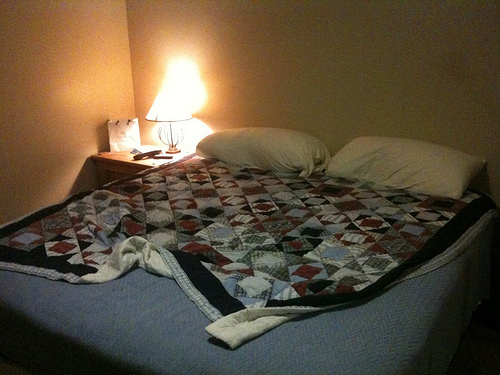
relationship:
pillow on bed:
[195, 125, 331, 178] [1, 128, 499, 374]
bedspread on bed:
[0, 148, 499, 349] [1, 128, 499, 374]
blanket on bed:
[1, 210, 500, 373] [1, 128, 499, 374]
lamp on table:
[145, 87, 194, 154] [90, 142, 194, 182]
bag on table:
[107, 117, 141, 152] [90, 142, 194, 182]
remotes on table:
[130, 148, 172, 162] [90, 142, 194, 182]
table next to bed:
[90, 142, 194, 182] [1, 128, 499, 374]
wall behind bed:
[126, 1, 499, 205] [1, 128, 499, 374]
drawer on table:
[105, 162, 144, 176] [90, 142, 194, 182]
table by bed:
[90, 142, 194, 182] [1, 128, 499, 374]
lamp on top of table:
[145, 87, 194, 154] [90, 142, 194, 182]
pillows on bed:
[195, 125, 487, 199] [1, 128, 499, 374]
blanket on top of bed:
[1, 210, 500, 373] [1, 128, 499, 374]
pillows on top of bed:
[195, 125, 487, 199] [1, 128, 499, 374]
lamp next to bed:
[145, 87, 194, 154] [1, 128, 499, 374]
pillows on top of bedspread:
[195, 125, 487, 199] [0, 148, 499, 349]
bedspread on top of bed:
[0, 148, 499, 349] [1, 128, 499, 374]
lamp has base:
[145, 87, 194, 154] [159, 123, 186, 153]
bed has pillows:
[1, 128, 499, 374] [195, 125, 487, 199]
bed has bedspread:
[1, 128, 499, 374] [0, 148, 499, 349]